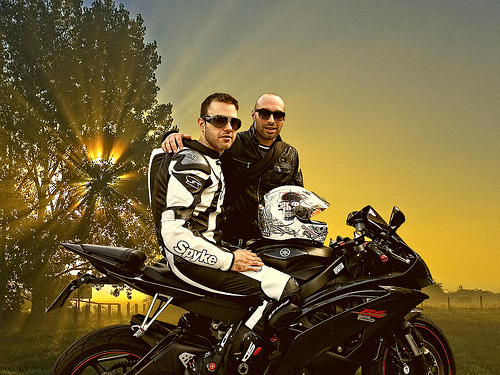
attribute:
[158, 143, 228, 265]
jacket — black, leather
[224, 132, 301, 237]
jacket — black, leather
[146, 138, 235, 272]
jacket — leather, white, black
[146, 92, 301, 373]
man — seated, posing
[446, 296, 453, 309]
rod — metal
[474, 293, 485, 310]
rod — metal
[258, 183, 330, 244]
helmet — white, black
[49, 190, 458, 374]
bike — black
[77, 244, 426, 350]
motorcycle — white, black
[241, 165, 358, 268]
helmet — black, white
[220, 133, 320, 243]
jacket — black, leather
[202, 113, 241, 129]
sunglasses — black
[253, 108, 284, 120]
sunglasses — black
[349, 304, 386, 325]
logo — red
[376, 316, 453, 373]
tire rim — red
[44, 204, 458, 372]
black motorcycle — red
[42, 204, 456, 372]
motorcycle — black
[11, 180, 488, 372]
motorcycle — black, red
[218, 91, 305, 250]
man — posing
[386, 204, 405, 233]
light — turn signal